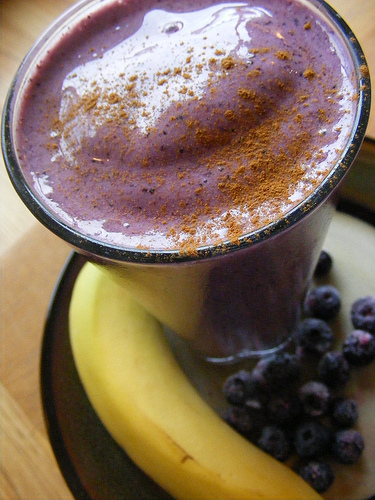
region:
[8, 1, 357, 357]
The liquid is purple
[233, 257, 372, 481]
The blueberries are blue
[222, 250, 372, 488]
The berries are round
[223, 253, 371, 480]
The berries are in a pile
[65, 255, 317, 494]
The banana is yellow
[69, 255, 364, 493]
The banana is next to the blueberries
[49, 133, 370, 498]
The plate is round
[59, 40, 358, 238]
The powder is brown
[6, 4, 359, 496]
The glass is on a plate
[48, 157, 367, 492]
Fruit on a plate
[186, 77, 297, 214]
a dusting of cinnamon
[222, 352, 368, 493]
a pile of blueberries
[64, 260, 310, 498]
an unpeeled banana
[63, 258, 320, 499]
a bright yellow banana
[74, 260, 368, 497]
a few fresh fruits and berries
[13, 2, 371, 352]
a purple berry smoothie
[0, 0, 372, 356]
a tall, full glass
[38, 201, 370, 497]
an earth colored plate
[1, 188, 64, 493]
a light, wood table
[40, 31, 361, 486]
a healthy snack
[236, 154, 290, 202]
the coca powder is on the top of the shake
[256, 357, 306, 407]
the blueberries are blue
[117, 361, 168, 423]
the banana is yellow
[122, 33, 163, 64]
the shake is purple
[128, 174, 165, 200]
the shake has blueberry pieces in it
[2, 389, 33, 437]
the table is tan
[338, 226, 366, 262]
the middle of the plate is white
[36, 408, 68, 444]
the ring on the plate is black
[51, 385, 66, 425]
the second ring is orange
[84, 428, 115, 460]
the thrid ring is olive green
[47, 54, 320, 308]
a breakfast smoothie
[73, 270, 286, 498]
a yellow banana on a plate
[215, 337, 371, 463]
blueberries on a dark plate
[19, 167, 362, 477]
a healthy balanced breakfast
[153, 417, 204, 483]
a brown spot on a banana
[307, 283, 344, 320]
one blue blueberry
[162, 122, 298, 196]
orange topping on a smoothie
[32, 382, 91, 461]
part of a black plate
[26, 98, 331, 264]
the top of a smoothie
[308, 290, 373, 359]
four blueberries on a plate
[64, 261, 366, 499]
a banana and blueberries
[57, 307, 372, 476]
fruit on a plate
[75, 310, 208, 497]
a yellow banana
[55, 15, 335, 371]
a smoothie in a glass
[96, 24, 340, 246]
orange powder on a smoothie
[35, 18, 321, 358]
a purple smoothie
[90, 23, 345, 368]
a blueberry and banana smoothie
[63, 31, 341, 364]
a fresh smoothie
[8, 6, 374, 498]
a plate of fruit and a smoothie on a wooden table